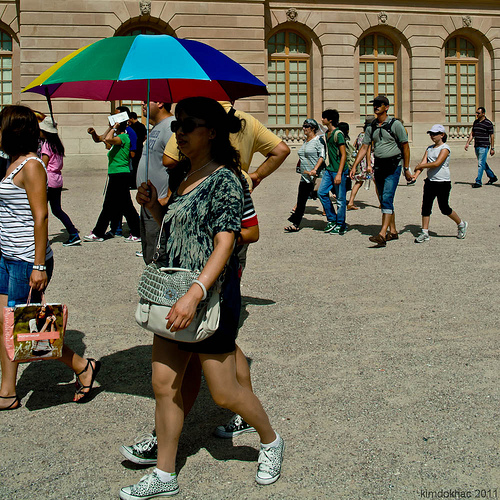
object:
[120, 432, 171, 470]
shoe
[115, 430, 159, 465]
foot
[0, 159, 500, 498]
ground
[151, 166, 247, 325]
shirt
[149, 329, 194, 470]
leg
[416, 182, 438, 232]
leg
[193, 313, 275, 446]
leg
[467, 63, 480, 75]
window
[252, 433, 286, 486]
shoe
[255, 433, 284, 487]
foot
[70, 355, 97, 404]
dress shoe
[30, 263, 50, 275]
watch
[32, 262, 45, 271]
wrist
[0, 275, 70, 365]
bag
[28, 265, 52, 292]
hand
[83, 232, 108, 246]
shoe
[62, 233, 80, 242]
shoe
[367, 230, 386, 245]
shoe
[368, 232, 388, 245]
foot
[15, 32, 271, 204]
umbrella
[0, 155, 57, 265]
tank top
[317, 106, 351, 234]
boy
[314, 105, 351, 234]
man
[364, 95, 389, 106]
hat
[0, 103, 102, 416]
woman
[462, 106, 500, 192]
people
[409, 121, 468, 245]
girl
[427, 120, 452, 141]
hat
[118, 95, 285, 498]
girl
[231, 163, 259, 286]
shirts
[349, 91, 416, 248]
man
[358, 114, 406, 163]
shirt